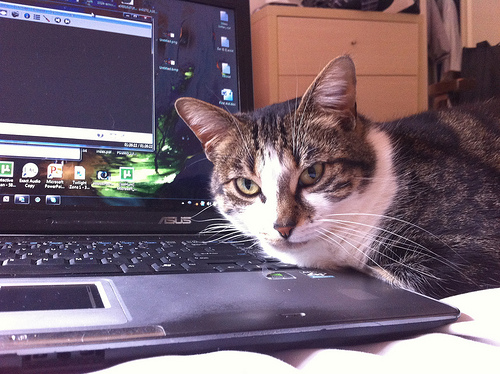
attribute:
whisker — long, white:
[322, 210, 483, 275]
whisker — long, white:
[324, 219, 481, 291]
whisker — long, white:
[313, 226, 388, 285]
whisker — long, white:
[236, 240, 259, 253]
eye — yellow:
[299, 159, 326, 188]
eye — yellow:
[223, 176, 268, 204]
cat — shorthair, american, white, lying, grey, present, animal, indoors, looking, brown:
[175, 53, 495, 296]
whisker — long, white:
[192, 201, 215, 217]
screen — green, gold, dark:
[0, 4, 236, 215]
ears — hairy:
[169, 58, 359, 155]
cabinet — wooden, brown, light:
[244, 5, 427, 127]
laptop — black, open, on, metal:
[0, 0, 461, 372]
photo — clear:
[1, 1, 500, 372]